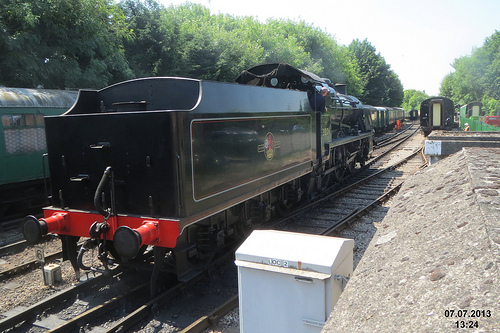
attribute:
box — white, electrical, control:
[234, 229, 355, 331]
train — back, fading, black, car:
[23, 60, 374, 287]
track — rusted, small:
[0, 117, 427, 332]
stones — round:
[3, 274, 55, 319]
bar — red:
[22, 205, 182, 257]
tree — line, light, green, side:
[0, 1, 404, 107]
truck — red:
[482, 114, 500, 130]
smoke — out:
[262, 44, 348, 83]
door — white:
[434, 100, 443, 130]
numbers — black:
[442, 306, 495, 330]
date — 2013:
[470, 308, 492, 317]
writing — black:
[452, 319, 485, 330]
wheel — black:
[299, 171, 331, 200]